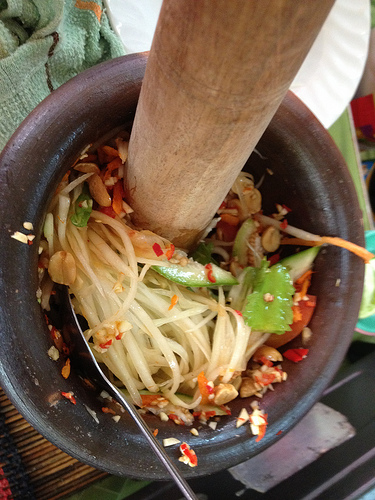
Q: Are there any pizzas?
A: No, there are no pizzas.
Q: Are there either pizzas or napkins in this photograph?
A: No, there are no pizzas or napkins.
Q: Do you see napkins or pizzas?
A: No, there are no pizzas or napkins.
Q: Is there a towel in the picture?
A: Yes, there is a towel.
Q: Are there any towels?
A: Yes, there is a towel.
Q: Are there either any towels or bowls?
A: Yes, there is a towel.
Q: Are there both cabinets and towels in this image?
A: No, there is a towel but no cabinets.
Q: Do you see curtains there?
A: No, there are no curtains.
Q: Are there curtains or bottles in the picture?
A: No, there are no curtains or bottles.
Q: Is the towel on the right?
A: No, the towel is on the left of the image.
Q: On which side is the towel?
A: The towel is on the left of the image.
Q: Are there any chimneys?
A: No, there are no chimneys.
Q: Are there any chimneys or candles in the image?
A: No, there are no chimneys or candles.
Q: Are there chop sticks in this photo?
A: No, there are no chop sticks.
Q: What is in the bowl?
A: The noodles are in the bowl.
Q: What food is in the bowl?
A: The food is noodles.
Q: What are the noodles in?
A: The noodles are in the bowl.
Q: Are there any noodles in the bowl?
A: Yes, there are noodles in the bowl.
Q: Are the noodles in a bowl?
A: Yes, the noodles are in a bowl.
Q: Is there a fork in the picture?
A: Yes, there is a fork.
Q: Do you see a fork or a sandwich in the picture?
A: Yes, there is a fork.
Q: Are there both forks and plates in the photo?
A: Yes, there are both a fork and a plate.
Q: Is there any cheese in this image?
A: No, there is no cheese.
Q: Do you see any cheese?
A: No, there is no cheese.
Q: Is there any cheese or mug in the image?
A: No, there are no cheese or mugs.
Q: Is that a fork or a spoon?
A: That is a fork.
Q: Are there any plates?
A: Yes, there is a plate.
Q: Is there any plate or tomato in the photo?
A: Yes, there is a plate.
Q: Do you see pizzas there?
A: No, there are no pizzas.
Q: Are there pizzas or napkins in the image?
A: No, there are no pizzas or napkins.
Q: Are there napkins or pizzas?
A: No, there are no pizzas or napkins.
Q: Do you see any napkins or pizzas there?
A: No, there are no pizzas or napkins.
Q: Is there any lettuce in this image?
A: Yes, there is lettuce.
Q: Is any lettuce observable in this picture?
A: Yes, there is lettuce.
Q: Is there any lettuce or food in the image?
A: Yes, there is lettuce.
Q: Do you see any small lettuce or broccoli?
A: Yes, there is small lettuce.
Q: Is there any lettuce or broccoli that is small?
A: Yes, the lettuce is small.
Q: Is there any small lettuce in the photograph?
A: Yes, there is small lettuce.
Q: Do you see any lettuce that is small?
A: Yes, there is lettuce that is small.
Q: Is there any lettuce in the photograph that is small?
A: Yes, there is lettuce that is small.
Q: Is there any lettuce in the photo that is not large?
A: Yes, there is small lettuce.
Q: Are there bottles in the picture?
A: No, there are no bottles.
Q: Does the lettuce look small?
A: Yes, the lettuce is small.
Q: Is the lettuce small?
A: Yes, the lettuce is small.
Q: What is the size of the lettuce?
A: The lettuce is small.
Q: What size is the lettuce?
A: The lettuce is small.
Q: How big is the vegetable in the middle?
A: The lettuce is small.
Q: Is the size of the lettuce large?
A: No, the lettuce is small.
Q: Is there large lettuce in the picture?
A: No, there is lettuce but it is small.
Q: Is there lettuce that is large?
A: No, there is lettuce but it is small.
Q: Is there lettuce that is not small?
A: No, there is lettuce but it is small.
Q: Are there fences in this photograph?
A: No, there are no fences.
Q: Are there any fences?
A: No, there are no fences.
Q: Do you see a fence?
A: No, there are no fences.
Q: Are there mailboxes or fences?
A: No, there are no fences or mailboxes.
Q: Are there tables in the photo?
A: Yes, there is a table.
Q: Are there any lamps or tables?
A: Yes, there is a table.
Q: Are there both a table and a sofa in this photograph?
A: No, there is a table but no sofas.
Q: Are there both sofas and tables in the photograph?
A: No, there is a table but no sofas.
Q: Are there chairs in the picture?
A: No, there are no chairs.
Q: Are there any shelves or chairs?
A: No, there are no chairs or shelves.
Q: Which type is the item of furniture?
A: The piece of furniture is a table.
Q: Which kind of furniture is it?
A: The piece of furniture is a table.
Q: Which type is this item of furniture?
A: That is a table.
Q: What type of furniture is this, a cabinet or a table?
A: That is a table.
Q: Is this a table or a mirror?
A: This is a table.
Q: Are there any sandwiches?
A: No, there are no sandwiches.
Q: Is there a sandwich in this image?
A: No, there are no sandwiches.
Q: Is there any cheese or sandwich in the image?
A: No, there are no sandwiches or cheese.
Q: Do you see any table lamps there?
A: No, there are no table lamps.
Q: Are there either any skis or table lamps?
A: No, there are no table lamps or skis.